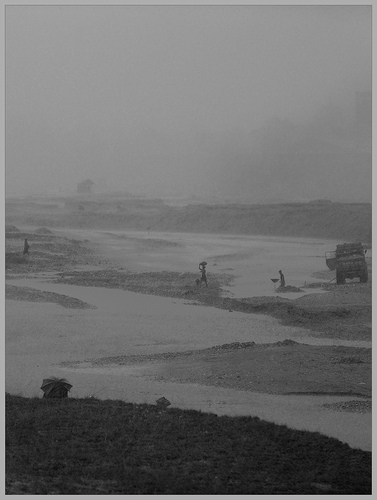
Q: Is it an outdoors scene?
A: Yes, it is outdoors.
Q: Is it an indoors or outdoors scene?
A: It is outdoors.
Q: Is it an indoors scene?
A: No, it is outdoors.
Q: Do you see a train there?
A: No, there are no trains.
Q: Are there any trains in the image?
A: No, there are no trains.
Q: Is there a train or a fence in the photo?
A: No, there are no trains or fences.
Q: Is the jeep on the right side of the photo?
A: Yes, the jeep is on the right of the image.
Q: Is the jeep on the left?
A: No, the jeep is on the right of the image.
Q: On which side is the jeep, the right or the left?
A: The jeep is on the right of the image.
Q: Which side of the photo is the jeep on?
A: The jeep is on the right of the image.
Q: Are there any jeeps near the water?
A: Yes, there is a jeep near the water.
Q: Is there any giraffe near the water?
A: No, there is a jeep near the water.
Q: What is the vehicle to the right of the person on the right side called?
A: The vehicle is a jeep.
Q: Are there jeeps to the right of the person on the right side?
A: Yes, there is a jeep to the right of the person.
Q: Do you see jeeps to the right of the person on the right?
A: Yes, there is a jeep to the right of the person.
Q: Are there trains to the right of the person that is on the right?
A: No, there is a jeep to the right of the person.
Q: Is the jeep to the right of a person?
A: Yes, the jeep is to the right of a person.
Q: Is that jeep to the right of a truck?
A: No, the jeep is to the right of a person.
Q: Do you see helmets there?
A: No, there are no helmets.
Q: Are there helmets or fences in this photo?
A: No, there are no helmets or fences.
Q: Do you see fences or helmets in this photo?
A: No, there are no helmets or fences.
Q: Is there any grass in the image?
A: Yes, there is grass.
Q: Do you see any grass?
A: Yes, there is grass.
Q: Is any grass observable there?
A: Yes, there is grass.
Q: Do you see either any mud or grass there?
A: Yes, there is grass.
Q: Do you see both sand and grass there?
A: Yes, there are both grass and sand.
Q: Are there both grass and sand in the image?
A: Yes, there are both grass and sand.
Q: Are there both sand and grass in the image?
A: Yes, there are both grass and sand.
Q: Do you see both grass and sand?
A: Yes, there are both grass and sand.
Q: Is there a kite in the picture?
A: No, there are no kites.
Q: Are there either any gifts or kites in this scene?
A: No, there are no kites or gifts.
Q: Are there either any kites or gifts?
A: No, there are no kites or gifts.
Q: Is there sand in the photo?
A: Yes, there is sand.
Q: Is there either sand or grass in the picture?
A: Yes, there is sand.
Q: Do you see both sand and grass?
A: Yes, there are both sand and grass.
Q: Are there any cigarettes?
A: No, there are no cigarettes.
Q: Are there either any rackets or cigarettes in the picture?
A: No, there are no cigarettes or rackets.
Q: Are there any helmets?
A: No, there are no helmets.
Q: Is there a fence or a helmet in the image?
A: No, there are no helmets or fences.